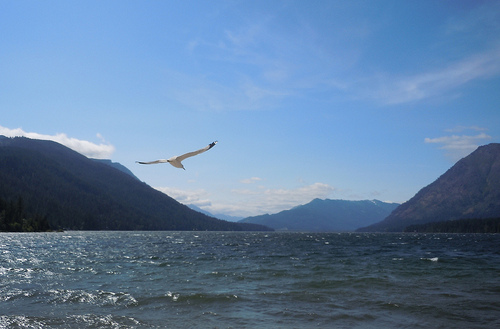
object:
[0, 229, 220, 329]
left side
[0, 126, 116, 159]
cloud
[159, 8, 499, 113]
cloud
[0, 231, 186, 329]
light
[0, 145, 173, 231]
plants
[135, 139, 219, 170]
bird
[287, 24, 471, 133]
air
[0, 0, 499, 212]
sky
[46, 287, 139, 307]
wave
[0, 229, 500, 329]
ocean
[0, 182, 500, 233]
trees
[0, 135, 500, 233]
mountains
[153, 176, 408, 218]
clouds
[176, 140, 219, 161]
wing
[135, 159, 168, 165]
wing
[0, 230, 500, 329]
water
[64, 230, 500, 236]
shore line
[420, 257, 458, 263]
wave